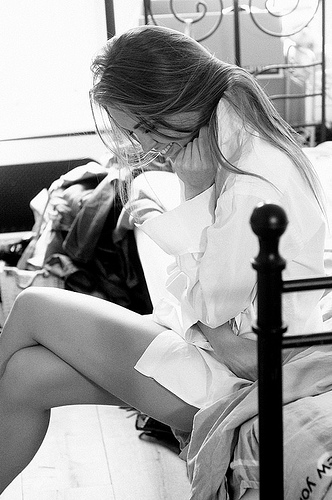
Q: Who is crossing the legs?
A: A woman.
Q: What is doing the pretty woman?
A: Looking down.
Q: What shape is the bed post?
A: Tubular.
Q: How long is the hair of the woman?
A: Long.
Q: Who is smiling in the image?
A: The woman.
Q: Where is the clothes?
A: In the corner in a heap.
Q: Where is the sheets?
A: On the bed.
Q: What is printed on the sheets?
A: New York.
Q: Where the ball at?
A: On top of the post.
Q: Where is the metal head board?
A: On the edge near the window.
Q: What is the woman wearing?
A: A white shirt.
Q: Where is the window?
A: Near the headboard of the bed.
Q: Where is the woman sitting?
A: On the bed.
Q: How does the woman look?
A: Happy.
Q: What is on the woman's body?
A: White shirt.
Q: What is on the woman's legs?
A: Nothing.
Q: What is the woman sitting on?
A: Bed.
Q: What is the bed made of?
A: Black metal.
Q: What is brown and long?
A: Woman's hair.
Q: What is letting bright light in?
A: Windows.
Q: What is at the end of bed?
A: Pile of clothes.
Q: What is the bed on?
A: Floor.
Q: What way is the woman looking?
A: Down.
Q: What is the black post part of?
A: Bed.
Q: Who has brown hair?
A: Young woman.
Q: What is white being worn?
A: Shirt.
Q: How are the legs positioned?
A: Crossed.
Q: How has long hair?
A: Young woman.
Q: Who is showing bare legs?
A: Young woman.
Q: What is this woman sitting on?
A: A bed.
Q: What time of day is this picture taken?
A: Day time.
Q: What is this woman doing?
A: Smiling.